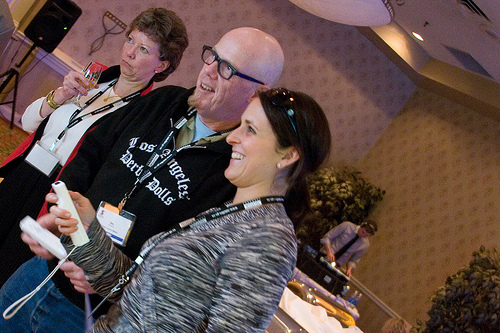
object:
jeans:
[0, 255, 90, 333]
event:
[0, 0, 499, 333]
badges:
[96, 200, 137, 247]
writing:
[118, 136, 191, 206]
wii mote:
[50, 180, 88, 249]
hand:
[45, 190, 96, 236]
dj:
[297, 239, 350, 295]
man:
[320, 220, 378, 278]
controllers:
[51, 180, 90, 247]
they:
[0, 7, 331, 332]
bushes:
[408, 243, 500, 333]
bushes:
[295, 165, 386, 251]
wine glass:
[67, 60, 103, 112]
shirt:
[0, 63, 156, 223]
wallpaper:
[355, 83, 499, 333]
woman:
[93, 87, 332, 333]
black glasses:
[201, 45, 265, 86]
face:
[193, 54, 248, 113]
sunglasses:
[267, 86, 298, 138]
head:
[223, 87, 331, 188]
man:
[0, 26, 283, 333]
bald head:
[215, 27, 285, 86]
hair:
[254, 87, 332, 234]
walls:
[56, 0, 499, 325]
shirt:
[59, 204, 299, 332]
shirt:
[175, 114, 233, 149]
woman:
[0, 7, 190, 288]